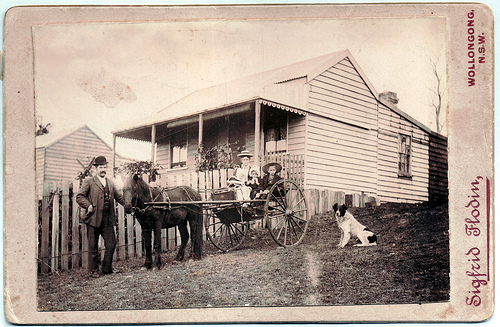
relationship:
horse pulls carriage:
[121, 169, 205, 270] [203, 178, 309, 248]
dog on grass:
[333, 201, 378, 247] [37, 200, 451, 308]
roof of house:
[114, 47, 439, 135] [114, 46, 449, 218]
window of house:
[265, 112, 287, 154] [114, 46, 449, 218]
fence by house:
[39, 153, 304, 276] [114, 46, 449, 218]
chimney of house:
[379, 90, 397, 105] [114, 46, 449, 218]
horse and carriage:
[121, 169, 205, 270] [203, 178, 309, 248]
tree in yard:
[428, 56, 442, 132] [368, 176, 445, 205]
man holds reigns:
[76, 155, 134, 278] [120, 190, 140, 212]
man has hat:
[76, 155, 134, 278] [94, 154, 110, 167]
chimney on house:
[379, 90, 397, 105] [114, 46, 449, 218]